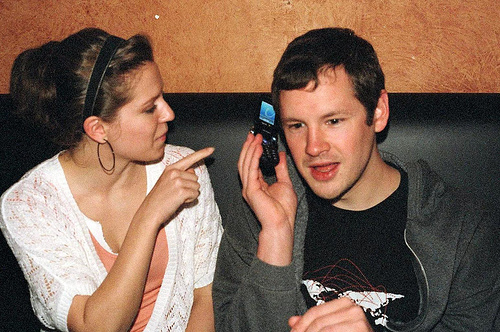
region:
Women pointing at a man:
[0, 26, 223, 330]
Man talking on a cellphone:
[211, 27, 498, 329]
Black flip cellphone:
[249, 97, 280, 168]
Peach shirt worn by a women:
[85, 223, 170, 330]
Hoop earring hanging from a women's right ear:
[95, 136, 115, 168]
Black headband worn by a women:
[80, 32, 125, 129]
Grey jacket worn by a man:
[210, 147, 495, 327]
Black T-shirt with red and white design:
[298, 159, 421, 329]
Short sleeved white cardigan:
[0, 144, 226, 329]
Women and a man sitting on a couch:
[2, 27, 498, 330]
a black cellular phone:
[244, 92, 292, 186]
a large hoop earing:
[88, 136, 120, 176]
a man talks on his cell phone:
[218, 19, 499, 329]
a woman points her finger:
[1, 22, 228, 329]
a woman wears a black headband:
[9, 22, 236, 329]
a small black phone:
[243, 87, 288, 174]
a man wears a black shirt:
[213, 19, 498, 330]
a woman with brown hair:
[0, 24, 223, 329]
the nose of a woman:
[156, 97, 176, 124]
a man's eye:
[321, 112, 346, 128]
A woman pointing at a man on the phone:
[3, 23, 492, 328]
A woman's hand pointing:
[139, 143, 221, 228]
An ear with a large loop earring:
[79, 112, 119, 176]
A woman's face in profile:
[111, 58, 179, 165]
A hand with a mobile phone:
[235, 96, 302, 233]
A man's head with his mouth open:
[273, 24, 395, 202]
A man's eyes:
[281, 107, 350, 133]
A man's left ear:
[370, 86, 393, 136]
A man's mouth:
[303, 156, 345, 187]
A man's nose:
[302, 123, 334, 159]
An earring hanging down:
[95, 142, 115, 169]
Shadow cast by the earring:
[105, 170, 113, 175]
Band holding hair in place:
[100, 55, 107, 64]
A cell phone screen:
[262, 106, 271, 118]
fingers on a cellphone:
[247, 135, 259, 157]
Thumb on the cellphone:
[279, 155, 284, 170]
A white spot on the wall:
[153, 14, 160, 19]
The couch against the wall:
[190, 105, 241, 140]